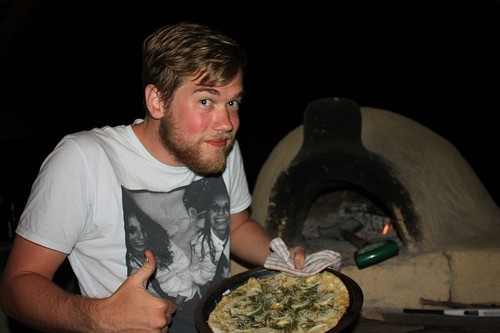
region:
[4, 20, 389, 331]
man holding plate with cloth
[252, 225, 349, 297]
cloth is white and plaid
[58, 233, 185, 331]
man has thumb up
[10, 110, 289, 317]
man wearing white shirt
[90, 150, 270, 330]
shirt has photograph on front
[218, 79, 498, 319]
stone oven in background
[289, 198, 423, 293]
shovel inside stone oven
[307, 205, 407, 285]
shovel has green handle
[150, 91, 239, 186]
man has brown beard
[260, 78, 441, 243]
stone oven has black opening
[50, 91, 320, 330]
a man holding a pizza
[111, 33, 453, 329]
a man holding a cooked pizza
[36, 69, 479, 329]
a man holding a baked pizza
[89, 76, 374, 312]
a man holding a small pizza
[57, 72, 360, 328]
a man holding a small cooked pizza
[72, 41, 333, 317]
a man holding a small baked pizza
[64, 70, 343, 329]
a man giving a thumbs up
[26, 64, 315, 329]
a man with a beard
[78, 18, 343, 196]
a man with blond hair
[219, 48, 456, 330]
a stone oven for cooking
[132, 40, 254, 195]
the man has beard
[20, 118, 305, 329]
the man is wearing a shirt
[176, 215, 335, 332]
man is holding a pie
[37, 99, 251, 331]
man is wearing a shirt